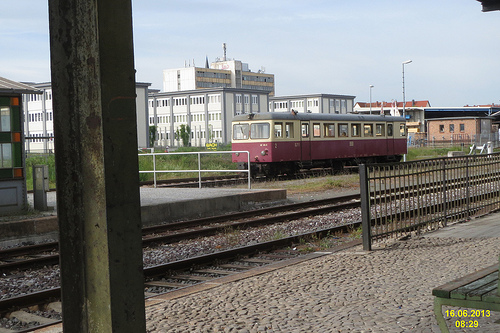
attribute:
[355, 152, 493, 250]
fence — metal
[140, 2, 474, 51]
sky — clear, blue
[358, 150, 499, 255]
fence — metal